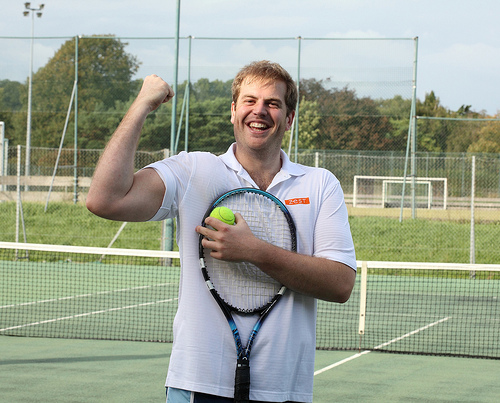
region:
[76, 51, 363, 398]
tennis player showing his muscles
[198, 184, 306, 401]
blue and black racket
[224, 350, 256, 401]
handle of racket is black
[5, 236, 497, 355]
a net in a tennis court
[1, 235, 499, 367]
net has white border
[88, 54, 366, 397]
man wears a white shirt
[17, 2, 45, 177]
a pole with four lights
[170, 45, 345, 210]
man smiles and is happy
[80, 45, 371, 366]
man holds a ball in left hand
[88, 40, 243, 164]
man makes a fist with right hand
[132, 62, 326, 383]
male tennis player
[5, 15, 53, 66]
white clouds against blue sky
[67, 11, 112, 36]
white clouds against blue sky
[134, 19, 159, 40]
white clouds against blue sky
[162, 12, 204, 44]
white clouds against blue sky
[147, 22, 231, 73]
white clouds against blue sky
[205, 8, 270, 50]
white clouds against blue sky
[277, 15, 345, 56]
white clouds against blue sky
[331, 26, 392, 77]
white clouds against blue sky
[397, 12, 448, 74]
white clouds against blue sky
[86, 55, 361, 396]
man making a fist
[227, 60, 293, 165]
man with huge smile on face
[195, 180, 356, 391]
man holding racket and ball in his arm.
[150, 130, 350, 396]
man wearing white polo shirt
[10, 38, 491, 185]
sport field surrounded by forest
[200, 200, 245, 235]
tennis ball is bright yellow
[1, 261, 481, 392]
tennis field ground is green with white lines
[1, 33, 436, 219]
tall net behind tennis field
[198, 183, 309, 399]
tennis racket is black, with blue and white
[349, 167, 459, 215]
soccer goals behind tennis court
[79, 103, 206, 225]
the arm of a tennis player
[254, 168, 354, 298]
the arm of a tennis player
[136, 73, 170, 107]
the hand of a tennis player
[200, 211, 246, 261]
the hand of a tennis player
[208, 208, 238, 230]
a bright yellow tennis ball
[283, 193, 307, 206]
an orange logo on a shirt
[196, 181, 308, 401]
a black white and blue tennis racket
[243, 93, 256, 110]
the eye on a face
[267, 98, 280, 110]
the eye on a face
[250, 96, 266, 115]
the nose on a face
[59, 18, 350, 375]
a man playing tennis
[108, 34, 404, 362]
a man holding a tennis racket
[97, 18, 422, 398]
a man holding a racket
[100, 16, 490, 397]
a man on a tennis court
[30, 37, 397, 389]
a tennis player on a court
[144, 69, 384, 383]
a man holding a ball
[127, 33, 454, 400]
a man holding a yellow ball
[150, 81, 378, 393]
a man holding a tennis ball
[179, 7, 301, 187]
a man that is smiling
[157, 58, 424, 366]
a man wearing a shirt